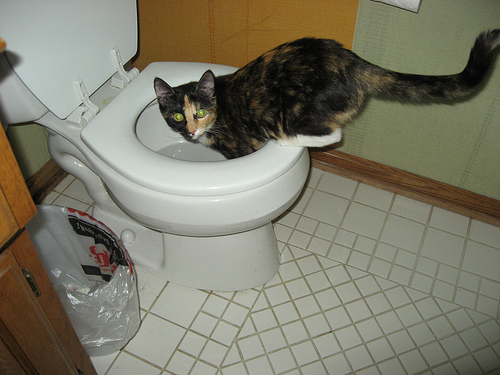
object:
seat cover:
[1, 1, 140, 120]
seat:
[81, 61, 306, 196]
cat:
[138, 33, 496, 154]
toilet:
[0, 4, 312, 290]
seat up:
[78, 58, 303, 198]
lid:
[0, 1, 142, 119]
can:
[33, 200, 153, 342]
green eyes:
[193, 107, 211, 120]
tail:
[362, 22, 499, 105]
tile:
[325, 304, 352, 329]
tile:
[352, 273, 379, 294]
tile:
[419, 339, 446, 364]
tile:
[249, 307, 277, 332]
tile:
[297, 251, 325, 273]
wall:
[126, 0, 499, 222]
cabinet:
[1, 233, 104, 374]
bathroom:
[0, 2, 499, 375]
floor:
[36, 162, 499, 374]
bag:
[20, 203, 143, 357]